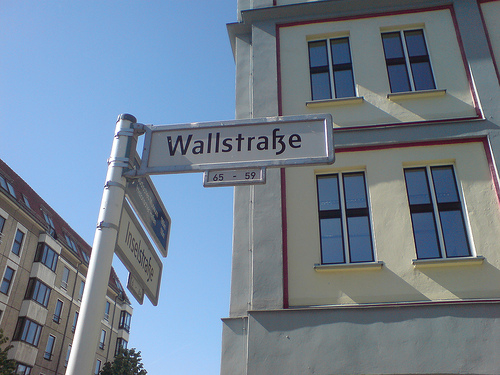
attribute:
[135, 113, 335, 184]
sign — white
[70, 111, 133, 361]
sign post — long, white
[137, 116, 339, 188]
sign — rectangular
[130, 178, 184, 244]
sign — blue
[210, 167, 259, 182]
numbers — black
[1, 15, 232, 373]
sky — bright blue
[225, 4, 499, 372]
building — tan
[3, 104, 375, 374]
street corner — city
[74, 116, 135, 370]
post — sign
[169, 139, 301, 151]
writing — black